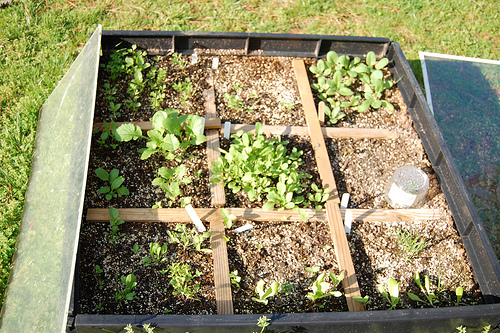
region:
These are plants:
[10, 5, 491, 330]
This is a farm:
[7, 6, 498, 331]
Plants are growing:
[103, 33, 482, 332]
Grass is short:
[3, 6, 70, 80]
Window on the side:
[409, 39, 499, 266]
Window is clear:
[415, 44, 499, 251]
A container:
[371, 159, 431, 206]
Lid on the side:
[8, 35, 99, 330]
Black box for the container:
[73, 7, 494, 332]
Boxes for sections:
[103, 43, 480, 315]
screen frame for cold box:
[6, 23, 109, 330]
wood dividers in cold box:
[76, 43, 444, 313]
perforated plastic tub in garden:
[379, 156, 431, 209]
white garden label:
[184, 203, 205, 231]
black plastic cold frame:
[56, 30, 495, 331]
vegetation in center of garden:
[215, 130, 322, 211]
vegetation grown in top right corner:
[313, 45, 400, 125]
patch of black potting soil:
[336, 125, 382, 202]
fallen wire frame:
[418, 42, 497, 277]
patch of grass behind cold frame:
[2, 2, 70, 79]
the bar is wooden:
[181, 67, 250, 272]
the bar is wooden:
[284, 98, 390, 302]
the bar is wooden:
[294, 92, 354, 262]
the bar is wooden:
[200, 191, 227, 328]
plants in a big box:
[297, 48, 404, 145]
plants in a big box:
[76, 15, 464, 329]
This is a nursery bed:
[45, 12, 483, 309]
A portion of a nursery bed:
[88, 25, 212, 126]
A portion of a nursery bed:
[87, 123, 222, 205]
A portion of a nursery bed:
[71, 209, 223, 311]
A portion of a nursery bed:
[205, 33, 310, 131]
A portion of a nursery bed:
[217, 118, 328, 212]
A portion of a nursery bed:
[224, 211, 346, 313]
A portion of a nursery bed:
[305, 36, 426, 126]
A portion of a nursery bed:
[322, 121, 444, 208]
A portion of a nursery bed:
[342, 206, 489, 328]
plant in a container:
[166, 159, 189, 187]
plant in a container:
[253, 278, 289, 305]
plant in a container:
[306, 278, 342, 309]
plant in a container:
[383, 270, 408, 296]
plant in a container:
[410, 278, 443, 302]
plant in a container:
[242, 146, 273, 193]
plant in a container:
[146, 125, 207, 208]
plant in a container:
[303, 43, 369, 113]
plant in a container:
[114, 62, 163, 111]